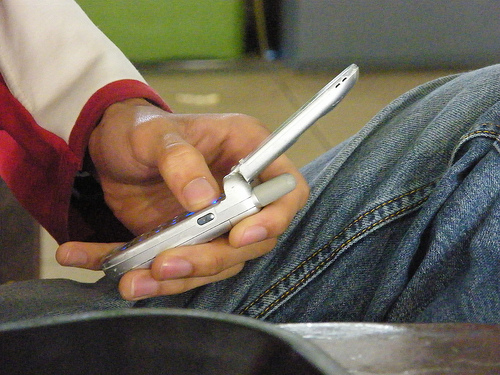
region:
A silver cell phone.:
[101, 59, 358, 279]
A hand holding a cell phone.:
[56, 60, 357, 300]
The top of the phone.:
[318, 60, 358, 108]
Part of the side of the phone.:
[176, 225, 208, 241]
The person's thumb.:
[154, 130, 219, 207]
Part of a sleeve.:
[51, 33, 94, 85]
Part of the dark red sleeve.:
[16, 154, 58, 203]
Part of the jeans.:
[392, 137, 433, 174]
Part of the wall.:
[345, 19, 387, 48]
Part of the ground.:
[225, 82, 294, 106]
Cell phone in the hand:
[50, 58, 364, 301]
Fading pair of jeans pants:
[0, 56, 499, 328]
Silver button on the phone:
[196, 209, 215, 226]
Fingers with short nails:
[50, 173, 267, 302]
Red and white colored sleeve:
[0, 0, 182, 250]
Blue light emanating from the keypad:
[95, 191, 224, 264]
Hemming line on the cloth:
[232, 118, 499, 326]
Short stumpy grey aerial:
[250, 167, 300, 208]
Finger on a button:
[159, 142, 224, 216]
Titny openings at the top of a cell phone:
[331, 72, 348, 94]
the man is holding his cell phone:
[93, 27, 391, 324]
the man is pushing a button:
[138, 106, 253, 227]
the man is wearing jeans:
[365, 41, 499, 211]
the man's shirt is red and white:
[9, 25, 148, 184]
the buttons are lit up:
[97, 158, 234, 270]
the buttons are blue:
[65, 164, 247, 282]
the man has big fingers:
[50, 164, 272, 316]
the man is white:
[65, 31, 295, 275]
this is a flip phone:
[62, 38, 392, 315]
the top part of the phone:
[198, 22, 421, 187]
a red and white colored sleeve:
[3, 2, 169, 247]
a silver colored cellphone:
[103, 63, 359, 282]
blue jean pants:
[0, 62, 499, 322]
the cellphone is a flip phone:
[99, 63, 357, 283]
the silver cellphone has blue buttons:
[99, 64, 357, 281]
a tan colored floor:
[40, 64, 477, 285]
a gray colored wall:
[282, 0, 497, 72]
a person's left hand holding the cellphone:
[53, 62, 361, 302]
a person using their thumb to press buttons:
[58, 67, 358, 298]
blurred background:
[79, 0, 499, 169]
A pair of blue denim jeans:
[396, 78, 491, 335]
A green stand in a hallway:
[134, 16, 244, 63]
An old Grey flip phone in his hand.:
[85, 70, 361, 281]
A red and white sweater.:
[0, 5, 147, 255]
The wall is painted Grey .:
[283, 8, 498, 65]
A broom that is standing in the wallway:
[247, 8, 288, 77]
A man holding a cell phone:
[57, 63, 377, 303]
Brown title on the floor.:
[159, 59, 301, 113]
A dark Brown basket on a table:
[0, 321, 367, 370]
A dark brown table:
[352, 329, 490, 374]